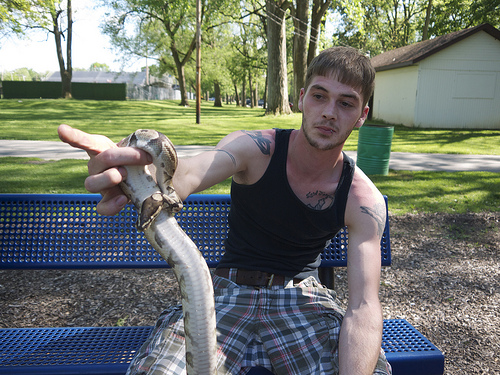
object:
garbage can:
[356, 121, 396, 179]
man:
[58, 47, 398, 374]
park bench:
[1, 314, 447, 375]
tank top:
[217, 128, 354, 285]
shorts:
[129, 270, 393, 374]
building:
[363, 20, 500, 132]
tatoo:
[303, 189, 338, 210]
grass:
[0, 99, 499, 212]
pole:
[193, 1, 205, 125]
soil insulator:
[0, 210, 500, 374]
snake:
[114, 130, 221, 374]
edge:
[2, 351, 447, 374]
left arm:
[335, 177, 389, 375]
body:
[116, 130, 219, 373]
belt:
[214, 267, 320, 287]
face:
[298, 46, 374, 153]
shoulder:
[220, 126, 289, 152]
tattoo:
[238, 128, 272, 156]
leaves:
[2, 0, 50, 31]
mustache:
[312, 120, 344, 133]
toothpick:
[329, 128, 334, 135]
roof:
[369, 22, 499, 74]